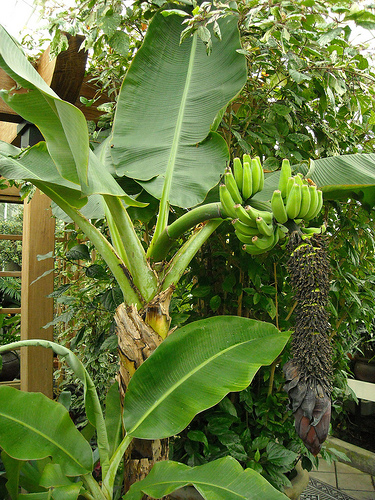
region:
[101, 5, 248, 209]
a large banana leaf.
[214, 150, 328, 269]
a bunch of green bananas.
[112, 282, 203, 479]
a banana tree with leaves.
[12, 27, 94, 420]
a section of a wooden structure.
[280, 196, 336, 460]
a tall banana tree.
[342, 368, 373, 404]
a section of a wooden structure.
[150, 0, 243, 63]
leaves from a tree.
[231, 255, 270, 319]
a section of a banana plant.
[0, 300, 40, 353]
a bunch of green plants.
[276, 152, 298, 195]
a green banana in a tree.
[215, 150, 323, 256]
bananas hanging on a tree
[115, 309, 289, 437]
green banana leaf growing on banana plant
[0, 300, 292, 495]
young green banana tree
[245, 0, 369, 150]
growing tree branches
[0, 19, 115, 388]
partial view of wood trellis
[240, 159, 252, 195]
banana fruit within a bunch of hanging bananas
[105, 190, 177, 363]
banana stalk on banana tree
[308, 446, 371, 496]
outdoor tile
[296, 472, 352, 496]
rug on tile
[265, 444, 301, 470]
plant leaf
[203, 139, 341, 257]
green bananas on tree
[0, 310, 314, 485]
three large green leaves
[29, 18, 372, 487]
banana tree with green fruit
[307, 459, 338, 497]
design on wooden ground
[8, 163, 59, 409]
wooden post beside banana tree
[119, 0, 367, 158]
small green leaves at top of tree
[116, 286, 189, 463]
yellowish trunk of tree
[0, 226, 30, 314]
three wooden rungs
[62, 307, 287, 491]
large green leaf with yellow stripe down center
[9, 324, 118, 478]
rolled up green leaf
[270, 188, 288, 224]
a banana hanging on a tree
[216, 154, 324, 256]
three clusters of bananas hanging on a tree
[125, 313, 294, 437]
a big green banana leaf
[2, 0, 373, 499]
a banana tree with clusters of bananas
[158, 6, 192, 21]
a small green leaf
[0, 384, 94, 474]
a single green banana leaf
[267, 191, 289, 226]
a not ripened green banana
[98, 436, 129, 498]
the stock from a banana leaf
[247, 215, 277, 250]
two green bananas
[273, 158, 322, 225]
a cluster of green bananas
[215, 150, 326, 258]
three green banana bunches w/ yellow tip ends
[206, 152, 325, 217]
many bananas stand inadvertently erect, & green, to be touched by the sun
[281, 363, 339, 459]
banana flower, enormous, red, purple, at end of rachis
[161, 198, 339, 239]
thick stem to bananas, rachis, flower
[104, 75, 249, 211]
gargantuan banana leaf stands upward, is slightly torn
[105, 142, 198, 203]
same semi-elephantine leaf is a bit folded where it connects to stem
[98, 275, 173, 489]
many leaves wrapped around banana pseudostem/stalk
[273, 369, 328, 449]
brachts of banana plant on/around female flower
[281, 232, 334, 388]
many bananas & flowers have been removed here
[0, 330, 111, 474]
a new, curling, yet-to-open banana leaf